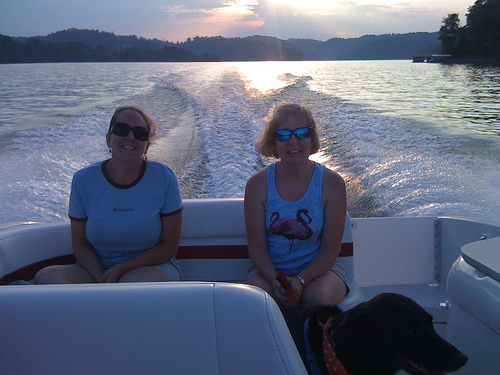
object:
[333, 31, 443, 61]
mountain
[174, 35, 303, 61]
mountain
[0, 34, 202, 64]
mountain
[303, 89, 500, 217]
wake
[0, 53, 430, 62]
shore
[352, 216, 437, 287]
door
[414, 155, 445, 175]
ground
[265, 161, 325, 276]
tank top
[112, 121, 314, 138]
sunglasses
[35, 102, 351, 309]
two women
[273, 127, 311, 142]
sunglasses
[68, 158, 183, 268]
tshirt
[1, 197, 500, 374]
boat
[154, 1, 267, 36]
sunset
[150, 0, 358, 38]
light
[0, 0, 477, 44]
clouds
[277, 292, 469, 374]
black lab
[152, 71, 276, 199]
wake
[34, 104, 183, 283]
ladies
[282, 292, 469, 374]
dog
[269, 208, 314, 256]
flamingos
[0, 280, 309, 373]
seat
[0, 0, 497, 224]
background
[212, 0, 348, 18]
sun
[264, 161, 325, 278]
flamingo shirt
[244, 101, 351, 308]
woman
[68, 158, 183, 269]
shirt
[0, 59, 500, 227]
water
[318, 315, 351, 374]
handkerchief